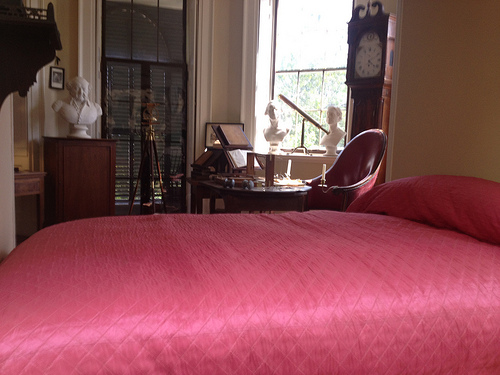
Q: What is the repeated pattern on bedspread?
A: Diamond.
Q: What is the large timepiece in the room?
A: Grandfather clock.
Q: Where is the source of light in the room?
A: Window.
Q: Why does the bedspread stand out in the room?
A: Hot pink.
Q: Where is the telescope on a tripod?
A: By glass doors.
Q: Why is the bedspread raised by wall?
A: Covering pillows.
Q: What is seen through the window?
A: Trees.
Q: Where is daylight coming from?
A: A window.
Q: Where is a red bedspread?
A: On the bed.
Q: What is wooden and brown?
A: Grandfather clock.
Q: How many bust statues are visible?
A: Three.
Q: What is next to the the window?
A: A grandfather clock.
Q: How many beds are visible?
A: One.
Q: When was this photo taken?
A: Inside, during the daytime.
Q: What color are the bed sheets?
A: Pink.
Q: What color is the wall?
A: Tan.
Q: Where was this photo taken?
A: A bedroom.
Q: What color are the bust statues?
A: White.